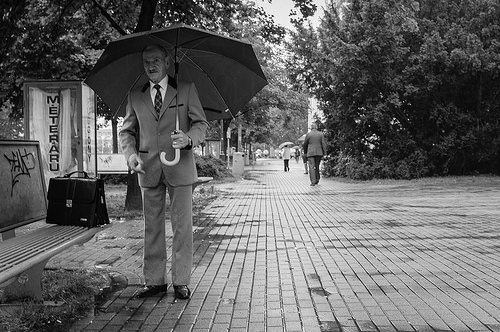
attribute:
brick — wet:
[206, 245, 218, 252]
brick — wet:
[320, 320, 338, 330]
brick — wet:
[222, 233, 232, 238]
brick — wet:
[102, 253, 120, 263]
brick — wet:
[194, 231, 206, 243]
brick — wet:
[189, 177, 496, 330]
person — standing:
[122, 46, 200, 300]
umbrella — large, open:
[89, 22, 266, 164]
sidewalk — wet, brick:
[218, 202, 388, 267]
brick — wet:
[260, 302, 307, 329]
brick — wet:
[265, 298, 281, 311]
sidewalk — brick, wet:
[46, 157, 498, 330]